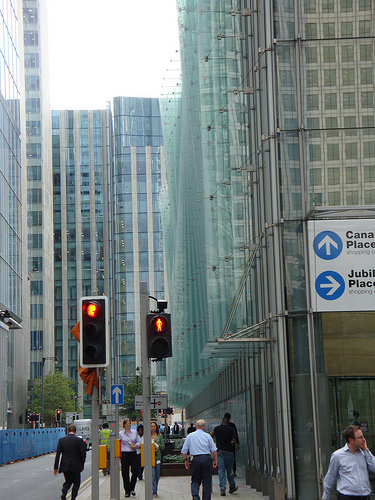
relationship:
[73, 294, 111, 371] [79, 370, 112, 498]
light on a pole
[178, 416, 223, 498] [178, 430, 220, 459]
man wearing a shirt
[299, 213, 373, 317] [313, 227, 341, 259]
sign has an arrow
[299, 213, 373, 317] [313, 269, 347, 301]
sign has an arrow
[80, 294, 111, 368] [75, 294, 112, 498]
light on pole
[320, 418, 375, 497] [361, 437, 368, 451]
man has a hand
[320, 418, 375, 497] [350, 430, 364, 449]
man has a face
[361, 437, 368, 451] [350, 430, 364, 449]
hand on h face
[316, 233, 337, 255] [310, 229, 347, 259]
arrow inside circle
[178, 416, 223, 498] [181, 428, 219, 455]
man wearing shirt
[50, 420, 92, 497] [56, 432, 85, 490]
man wearing suit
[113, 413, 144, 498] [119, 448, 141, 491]
woman wearing pants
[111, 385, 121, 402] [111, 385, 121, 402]
arrow on arrow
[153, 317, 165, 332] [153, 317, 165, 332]
light on light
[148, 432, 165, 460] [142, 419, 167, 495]
shirt on woman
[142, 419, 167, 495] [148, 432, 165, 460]
woman wearing shirt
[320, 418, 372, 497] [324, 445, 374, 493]
man wearing shirt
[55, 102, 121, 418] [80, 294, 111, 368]
building behind light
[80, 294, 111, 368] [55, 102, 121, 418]
light in front of building